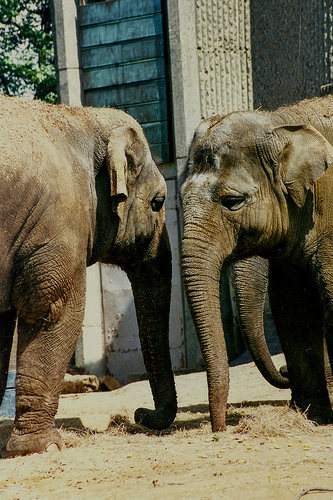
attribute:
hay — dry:
[54, 399, 318, 452]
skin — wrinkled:
[173, 183, 225, 303]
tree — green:
[1, 2, 59, 103]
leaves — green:
[9, 8, 15, 14]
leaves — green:
[30, 75, 36, 79]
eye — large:
[213, 187, 251, 214]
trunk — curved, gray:
[182, 226, 236, 431]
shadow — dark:
[103, 402, 248, 432]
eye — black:
[218, 190, 248, 210]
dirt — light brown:
[130, 405, 301, 469]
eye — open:
[218, 185, 249, 220]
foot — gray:
[19, 415, 77, 454]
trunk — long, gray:
[178, 216, 233, 434]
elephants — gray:
[0, 98, 321, 445]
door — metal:
[100, 173, 188, 379]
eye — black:
[150, 197, 166, 212]